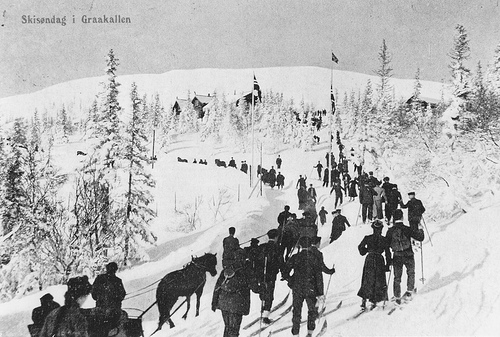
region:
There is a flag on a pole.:
[240, 70, 270, 197]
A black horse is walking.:
[145, 254, 221, 334]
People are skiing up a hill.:
[179, 181, 480, 328]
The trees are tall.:
[51, 38, 179, 265]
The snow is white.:
[161, 174, 245, 226]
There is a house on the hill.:
[168, 92, 233, 131]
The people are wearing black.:
[206, 201, 371, 335]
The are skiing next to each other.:
[353, 209, 433, 319]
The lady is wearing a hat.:
[61, 271, 94, 335]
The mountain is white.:
[15, 58, 450, 121]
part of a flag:
[321, 50, 349, 72]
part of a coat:
[293, 261, 319, 288]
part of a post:
[245, 122, 257, 174]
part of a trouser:
[305, 301, 317, 324]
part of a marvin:
[227, 224, 239, 236]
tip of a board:
[330, 295, 348, 314]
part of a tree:
[129, 193, 154, 249]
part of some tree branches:
[135, 158, 173, 242]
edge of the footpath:
[244, 173, 258, 216]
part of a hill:
[331, 4, 368, 34]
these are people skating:
[228, 200, 318, 335]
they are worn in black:
[220, 251, 321, 328]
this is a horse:
[157, 249, 215, 320]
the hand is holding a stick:
[418, 227, 424, 284]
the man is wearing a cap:
[300, 235, 309, 244]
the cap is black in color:
[301, 235, 311, 242]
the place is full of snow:
[437, 215, 497, 335]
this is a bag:
[218, 272, 237, 307]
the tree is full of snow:
[16, 118, 146, 253]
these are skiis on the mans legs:
[275, 294, 288, 326]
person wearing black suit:
[244, 197, 337, 332]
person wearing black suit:
[288, 208, 328, 332]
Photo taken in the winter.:
[6, 6, 484, 323]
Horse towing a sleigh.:
[143, 255, 229, 320]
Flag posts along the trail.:
[238, 34, 356, 221]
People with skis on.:
[212, 228, 438, 332]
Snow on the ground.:
[4, 60, 492, 326]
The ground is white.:
[0, 58, 496, 328]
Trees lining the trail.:
[6, 55, 165, 277]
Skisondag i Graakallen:
[2, 12, 153, 28]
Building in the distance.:
[134, 85, 288, 146]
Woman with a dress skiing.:
[352, 192, 396, 324]